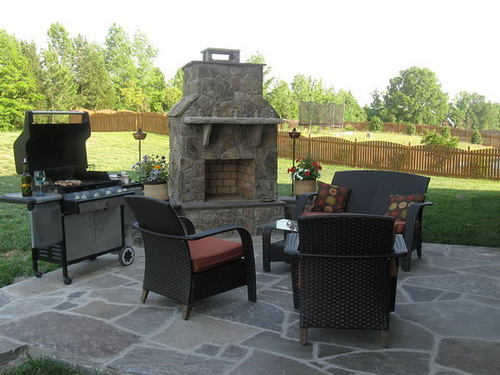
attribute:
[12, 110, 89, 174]
lid — open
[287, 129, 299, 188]
light — tall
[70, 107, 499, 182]
fence — brown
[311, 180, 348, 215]
pillow — designed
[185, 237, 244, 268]
cushion — dark red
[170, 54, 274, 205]
fireplace — stone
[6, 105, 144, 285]
gas grill — on the patio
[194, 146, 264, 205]
fireplace — pictured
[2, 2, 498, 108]
sky — clear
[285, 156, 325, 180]
flowers — red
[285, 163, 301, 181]
flower — red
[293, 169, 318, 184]
flower — red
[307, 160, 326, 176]
flower — red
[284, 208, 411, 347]
chair — wicker, black, large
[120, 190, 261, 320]
chair — large, black, wicker, brown, outdoor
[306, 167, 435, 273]
chair — wicker, large, black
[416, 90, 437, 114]
tree leaves — green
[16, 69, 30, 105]
tree leaves — green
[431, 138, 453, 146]
tree leaves — green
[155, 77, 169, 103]
tree leaves — green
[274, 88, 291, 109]
tree leaves — green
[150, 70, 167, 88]
tree leaves — green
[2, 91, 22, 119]
tree leaves — green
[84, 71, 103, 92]
tree leaves — green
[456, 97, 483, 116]
tree leaves — green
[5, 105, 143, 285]
grill — outdoor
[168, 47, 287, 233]
fire place — outdoor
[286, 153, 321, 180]
flowers — red and white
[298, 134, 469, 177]
fence — wood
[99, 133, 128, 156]
grass — green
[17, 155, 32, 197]
bottle — green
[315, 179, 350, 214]
pillow — square